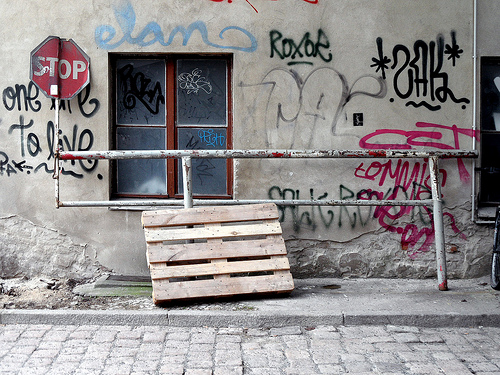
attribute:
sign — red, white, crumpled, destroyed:
[30, 35, 91, 99]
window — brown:
[110, 54, 235, 201]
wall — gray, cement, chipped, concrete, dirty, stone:
[1, 1, 496, 277]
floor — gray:
[5, 278, 499, 374]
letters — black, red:
[1, 1, 476, 253]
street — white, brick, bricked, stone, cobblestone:
[1, 325, 496, 374]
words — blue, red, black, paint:
[2, 1, 476, 256]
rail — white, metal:
[55, 151, 479, 290]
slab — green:
[89, 279, 152, 295]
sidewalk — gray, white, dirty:
[1, 278, 497, 315]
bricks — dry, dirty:
[1, 325, 497, 375]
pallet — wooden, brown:
[142, 204, 293, 301]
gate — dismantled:
[55, 149, 478, 292]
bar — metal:
[55, 150, 478, 159]